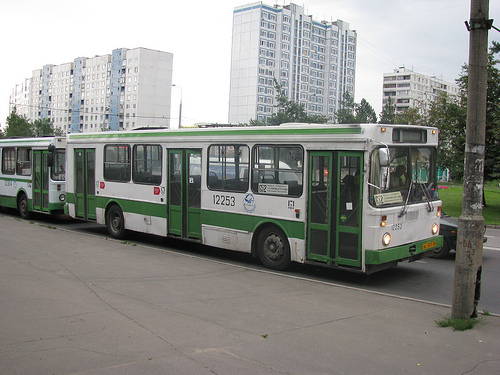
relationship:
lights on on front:
[379, 208, 448, 247] [363, 115, 444, 277]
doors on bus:
[307, 152, 368, 271] [49, 118, 446, 282]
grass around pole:
[435, 314, 482, 331] [448, 0, 491, 324]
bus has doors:
[62, 111, 457, 283] [73, 139, 358, 250]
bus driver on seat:
[389, 159, 412, 193] [386, 173, 401, 192]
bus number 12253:
[9, 111, 456, 283] [213, 195, 238, 206]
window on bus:
[251, 144, 303, 199] [0, 122, 444, 276]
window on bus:
[203, 144, 249, 195] [0, 122, 444, 276]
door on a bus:
[62, 147, 88, 219] [63, 98, 459, 263]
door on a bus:
[72, 147, 89, 219] [63, 98, 459, 263]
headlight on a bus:
[381, 236, 394, 244] [49, 118, 446, 282]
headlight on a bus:
[428, 220, 440, 233] [49, 118, 446, 282]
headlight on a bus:
[55, 190, 67, 202] [1, 133, 64, 225]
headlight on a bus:
[381, 232, 394, 244] [49, 118, 446, 282]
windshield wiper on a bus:
[399, 175, 414, 217] [49, 118, 446, 282]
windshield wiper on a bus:
[415, 170, 434, 215] [49, 118, 446, 282]